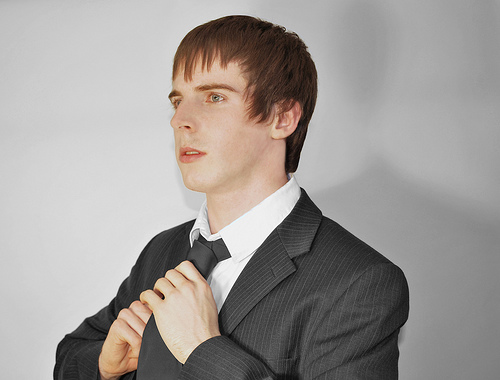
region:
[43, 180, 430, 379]
the man's jacket is pinstripe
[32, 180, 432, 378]
the man's jacket is dark grey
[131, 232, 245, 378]
the man is tying his tie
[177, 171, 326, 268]
the man's shirt has a collar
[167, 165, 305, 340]
the man's shirt is white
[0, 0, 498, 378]
the wall behind the man is white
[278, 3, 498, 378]
the man is casting a shadow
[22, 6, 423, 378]
the man is not looking at the camera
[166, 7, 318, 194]
the man has brown hair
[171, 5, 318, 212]
the man has short hair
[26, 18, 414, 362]
The man is wearing a grey suit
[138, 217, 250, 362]
The man is wearing a black tie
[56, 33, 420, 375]
The man is adjusting his tie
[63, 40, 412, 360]
The man has a white dress shirt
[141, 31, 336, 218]
The man has brown hair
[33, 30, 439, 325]
White wall behind man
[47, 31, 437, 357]
The man has his mouth slightly open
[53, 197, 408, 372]
The suit has grey stripes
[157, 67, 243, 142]
The man has green eyes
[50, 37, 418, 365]
The man is looking towards his right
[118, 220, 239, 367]
a long black tie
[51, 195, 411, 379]
a striped black jacket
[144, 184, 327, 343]
a white collard shirt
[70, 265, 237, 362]
a pair of pale hands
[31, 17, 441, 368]
a man in professional clothing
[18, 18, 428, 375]
a man tying his tie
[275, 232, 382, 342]
a few thin pinstripes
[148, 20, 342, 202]
a man with short red hair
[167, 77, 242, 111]
a pair of pale eyes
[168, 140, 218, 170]
a mouth with red lips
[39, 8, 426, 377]
young man wearing a suit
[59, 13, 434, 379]
young man fixing his tie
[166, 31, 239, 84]
bangs laying on the forehead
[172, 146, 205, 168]
mouth slightly open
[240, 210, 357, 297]
collar is down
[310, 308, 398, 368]
wrinkles in the suit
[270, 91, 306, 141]
hair laying on the ear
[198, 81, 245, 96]
long, thin eyebrow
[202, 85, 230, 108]
green eye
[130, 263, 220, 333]
fingers clasped around the tie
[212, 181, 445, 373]
grey pin striped suit coat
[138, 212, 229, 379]
tieing a necktie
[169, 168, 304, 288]
a white dress shirt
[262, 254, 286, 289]
a button hole in a lapel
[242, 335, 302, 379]
pocket in the suit coat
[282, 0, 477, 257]
man's shadow on a white wall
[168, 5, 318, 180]
a feathered hair cut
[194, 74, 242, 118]
a green eye with red eyebrow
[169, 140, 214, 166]
pink lips parted to show white teeth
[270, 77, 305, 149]
hair feathered over left ear